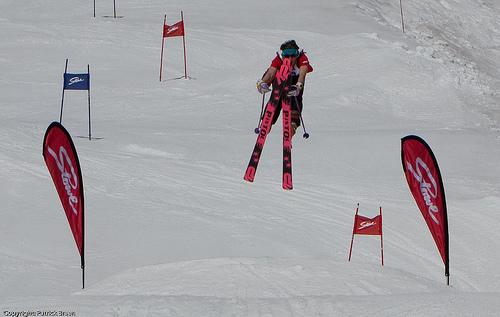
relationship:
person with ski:
[243, 40, 313, 191] [243, 64, 288, 182]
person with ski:
[243, 40, 313, 191] [281, 57, 294, 190]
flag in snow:
[42, 121, 85, 290] [0, 0, 499, 317]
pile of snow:
[115, 142, 185, 159] [0, 0, 499, 317]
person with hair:
[243, 40, 313, 191] [280, 40, 307, 59]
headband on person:
[281, 48, 299, 55] [243, 40, 313, 191]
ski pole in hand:
[288, 76, 310, 139] [287, 84, 300, 99]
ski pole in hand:
[254, 91, 265, 134] [256, 81, 271, 94]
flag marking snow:
[159, 11, 188, 83] [0, 0, 499, 317]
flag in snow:
[159, 11, 188, 83] [0, 0, 499, 317]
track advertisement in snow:
[59, 58, 91, 141] [0, 0, 499, 317]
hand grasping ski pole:
[287, 84, 300, 99] [288, 76, 310, 139]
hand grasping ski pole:
[256, 81, 271, 94] [254, 91, 265, 134]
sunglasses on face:
[281, 53, 299, 58] [280, 52, 299, 67]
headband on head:
[281, 48, 299, 55] [281, 40, 300, 68]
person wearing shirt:
[243, 40, 313, 191] [269, 50, 313, 85]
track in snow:
[184, 27, 273, 86] [0, 0, 499, 317]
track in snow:
[0, 124, 447, 275] [0, 0, 499, 317]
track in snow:
[69, 20, 163, 40] [0, 0, 499, 317]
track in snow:
[235, 258, 293, 298] [0, 0, 499, 317]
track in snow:
[0, 155, 54, 181] [0, 0, 499, 317]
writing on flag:
[46, 144, 78, 215] [42, 121, 85, 290]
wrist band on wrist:
[295, 82, 304, 89] [294, 81, 303, 94]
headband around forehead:
[281, 48, 299, 55] [281, 46, 298, 57]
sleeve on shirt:
[297, 52, 313, 74] [269, 50, 313, 85]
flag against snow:
[159, 11, 188, 83] [0, 0, 499, 317]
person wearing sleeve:
[243, 40, 313, 191] [297, 52, 313, 74]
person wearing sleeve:
[243, 40, 313, 191] [270, 56, 283, 73]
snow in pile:
[0, 0, 499, 317] [72, 255, 462, 299]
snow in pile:
[0, 0, 499, 317] [115, 142, 185, 159]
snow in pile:
[0, 0, 499, 317] [446, 195, 499, 223]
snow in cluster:
[0, 0, 499, 317] [416, 44, 435, 57]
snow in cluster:
[0, 0, 499, 317] [456, 58, 466, 67]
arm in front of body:
[286, 53, 308, 98] [273, 51, 304, 107]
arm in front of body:
[257, 51, 281, 93] [273, 51, 304, 107]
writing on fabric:
[46, 144, 78, 215] [43, 126, 83, 257]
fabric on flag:
[43, 126, 83, 257] [42, 121, 85, 290]